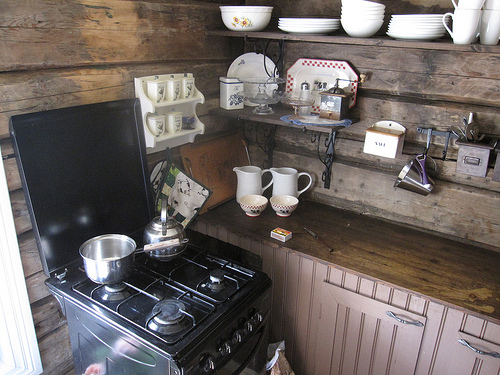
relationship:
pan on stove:
[78, 232, 144, 283] [52, 252, 284, 374]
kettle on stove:
[148, 205, 190, 261] [52, 252, 284, 374]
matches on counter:
[266, 222, 298, 244] [210, 202, 498, 316]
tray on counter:
[173, 138, 260, 207] [210, 202, 498, 316]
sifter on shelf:
[313, 83, 354, 121] [221, 98, 346, 133]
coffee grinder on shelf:
[316, 75, 359, 120] [221, 98, 346, 133]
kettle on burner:
[148, 205, 190, 261] [140, 240, 197, 268]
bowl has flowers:
[215, 9, 275, 29] [232, 16, 252, 28]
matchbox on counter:
[266, 222, 298, 244] [210, 202, 498, 316]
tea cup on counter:
[235, 193, 271, 221] [210, 202, 498, 316]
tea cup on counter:
[270, 194, 302, 214] [210, 202, 498, 316]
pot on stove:
[78, 232, 144, 283] [52, 252, 284, 374]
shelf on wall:
[142, 122, 207, 140] [5, 4, 261, 201]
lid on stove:
[8, 94, 157, 273] [52, 252, 284, 374]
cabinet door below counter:
[323, 280, 421, 374] [210, 202, 498, 316]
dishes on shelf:
[275, 13, 341, 35] [215, 28, 490, 55]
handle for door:
[388, 309, 423, 328] [323, 280, 421, 374]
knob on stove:
[250, 311, 266, 323] [52, 252, 284, 374]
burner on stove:
[140, 240, 197, 268] [52, 252, 284, 374]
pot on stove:
[79, 231, 137, 280] [52, 252, 284, 374]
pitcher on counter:
[229, 160, 271, 195] [210, 202, 498, 316]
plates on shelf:
[388, 8, 450, 39] [215, 28, 490, 55]